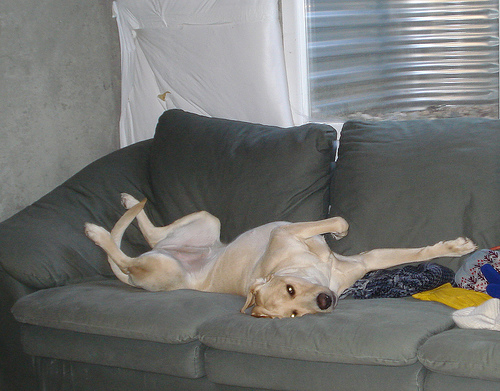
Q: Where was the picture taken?
A: In a living room.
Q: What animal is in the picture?
A: A dog.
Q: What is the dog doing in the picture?
A: Laying.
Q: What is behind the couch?
A: A window.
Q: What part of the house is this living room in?
A: A basement.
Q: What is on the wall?
A: Plastic.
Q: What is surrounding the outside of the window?
A: Metal.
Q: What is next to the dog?
A: A scarf.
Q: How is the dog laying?
A: Upside down.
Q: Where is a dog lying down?
A: On a couch.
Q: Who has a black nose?
A: The dog.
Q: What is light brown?
A: The dog.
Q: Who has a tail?
A: Dog on couch.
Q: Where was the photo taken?
A: In a house.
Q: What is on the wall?
A: White plastic tarp.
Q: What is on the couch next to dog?
A: Pile of fabric.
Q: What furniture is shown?
A: Couch.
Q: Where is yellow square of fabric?
A: On couch.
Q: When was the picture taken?
A: Daytime.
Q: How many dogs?
A: One.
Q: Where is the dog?
A: On the couch.